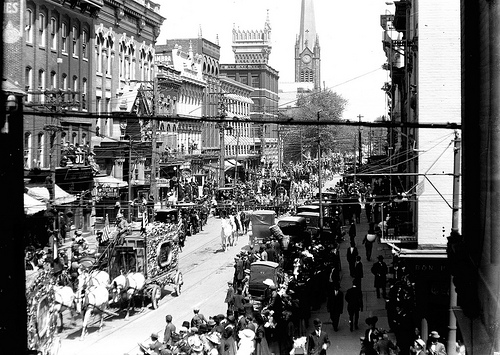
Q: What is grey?
A: Streets.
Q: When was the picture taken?
A: Daytime.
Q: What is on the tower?
A: Clock.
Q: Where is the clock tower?
A: Back and middle of picture.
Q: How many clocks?
A: One.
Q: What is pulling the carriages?
A: Horses.